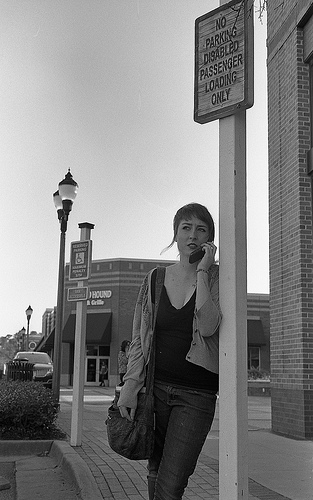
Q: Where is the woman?
A: Next to the pole.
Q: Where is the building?
A: Across the street.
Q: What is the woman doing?
A: Talking on her phone.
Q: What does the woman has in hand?
A: Cellphone.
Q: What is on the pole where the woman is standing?
A: No parking sign.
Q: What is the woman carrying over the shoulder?
A: Purse.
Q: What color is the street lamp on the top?
A: Black.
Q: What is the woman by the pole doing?
A: Talking on cellphone.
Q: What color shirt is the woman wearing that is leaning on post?
A: Black.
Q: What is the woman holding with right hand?
A: Cellphone.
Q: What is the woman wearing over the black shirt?
A: Sweater.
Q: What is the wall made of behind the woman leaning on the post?
A: Bricks.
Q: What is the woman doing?
A: Talking on the phone.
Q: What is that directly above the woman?
A: A sign.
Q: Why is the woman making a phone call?
A: Her car broke down.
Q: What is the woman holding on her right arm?
A: A handbag.